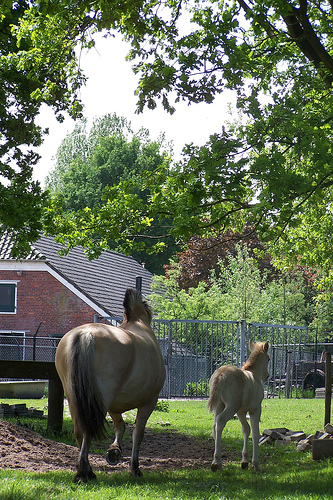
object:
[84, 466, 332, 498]
shadow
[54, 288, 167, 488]
animals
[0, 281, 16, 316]
window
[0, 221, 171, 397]
building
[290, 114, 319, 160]
leaves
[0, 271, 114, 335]
bricks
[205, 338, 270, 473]
brown foal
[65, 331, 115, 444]
tail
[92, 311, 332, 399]
fence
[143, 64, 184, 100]
leaves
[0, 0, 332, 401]
tree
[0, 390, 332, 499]
ground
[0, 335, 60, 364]
fence